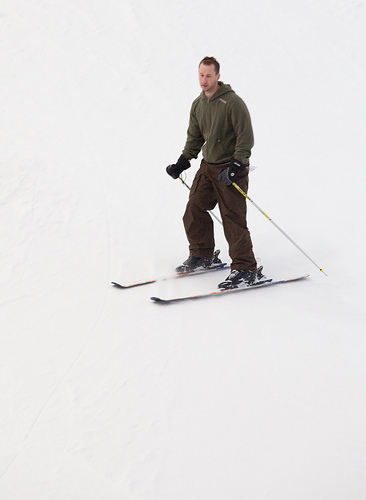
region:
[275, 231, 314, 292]
There is a ski pole that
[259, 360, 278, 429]
There is bright, white snow here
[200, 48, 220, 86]
This man has a head full of brown hair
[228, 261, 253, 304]
This man has a pair of black ski boots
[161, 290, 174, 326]
There are some colorful skis here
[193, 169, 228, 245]
There are some olive pants this man has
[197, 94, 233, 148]
This man has a khaki sweatshirt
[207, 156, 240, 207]
This man has black gloves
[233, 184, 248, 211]
There is a yellow sticker that is there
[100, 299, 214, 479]
This photo was taken in the early afternoon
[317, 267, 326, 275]
yellow near the tip of the pole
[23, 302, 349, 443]
the snow is very white and smooth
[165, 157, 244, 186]
black and grey gloves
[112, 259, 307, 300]
black ski boots on white skis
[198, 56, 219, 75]
the short hair of a man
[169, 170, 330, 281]
yellow and white ski poles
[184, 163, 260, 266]
man is wearing brown pants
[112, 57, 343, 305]
a man is snow skiing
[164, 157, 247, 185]
man is wearing black and gray gloves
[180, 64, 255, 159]
man is wearing hooded jacket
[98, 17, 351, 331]
the man is skiing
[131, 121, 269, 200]
the man is wearing gloves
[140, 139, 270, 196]
the gloves are grey and black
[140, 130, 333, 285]
the man is holding ski poles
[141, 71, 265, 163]
the hoodie is hunter green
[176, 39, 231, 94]
the man is not wearing a hat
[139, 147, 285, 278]
the pants are brown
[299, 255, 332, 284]
the tip of the pole is pointy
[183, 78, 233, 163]
the jacket is zipped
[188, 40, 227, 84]
the man`s hair is short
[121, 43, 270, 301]
man on skis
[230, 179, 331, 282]
yellow marking on ski pole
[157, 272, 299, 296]
skis are red and white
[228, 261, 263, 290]
boots on foot is black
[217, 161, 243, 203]
black glove on left hand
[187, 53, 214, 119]
person looking down at ground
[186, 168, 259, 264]
brown pants on the man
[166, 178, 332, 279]
man holding two ski poles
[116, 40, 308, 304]
man skiing down white hillside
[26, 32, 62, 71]
white snow on hill side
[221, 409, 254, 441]
white snow on hill side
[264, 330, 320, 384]
white snow on hill side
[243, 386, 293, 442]
white snow on hill side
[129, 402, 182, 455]
white snow on hill side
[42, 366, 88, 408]
white snow on hill side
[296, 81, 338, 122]
white snow on hill side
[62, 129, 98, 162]
white snow on hill side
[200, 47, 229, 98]
the head of a man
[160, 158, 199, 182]
the right hand of a man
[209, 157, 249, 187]
the left hand of a man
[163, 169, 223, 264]
the right leg of a man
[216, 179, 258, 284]
the left leg of a man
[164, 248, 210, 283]
the right foot of a man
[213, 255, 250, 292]
the left foot of a man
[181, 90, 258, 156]
the jacket of a man